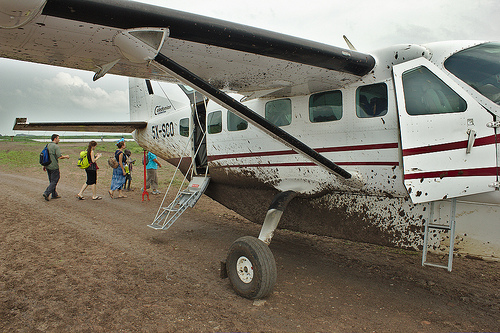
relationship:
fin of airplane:
[0, 93, 115, 156] [97, 15, 454, 283]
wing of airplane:
[31, 19, 353, 110] [97, 15, 454, 283]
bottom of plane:
[219, 187, 464, 266] [97, 15, 454, 283]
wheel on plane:
[204, 214, 295, 319] [213, 83, 441, 226]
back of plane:
[141, 66, 256, 137] [213, 83, 441, 226]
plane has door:
[213, 83, 441, 226] [374, 41, 486, 227]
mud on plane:
[280, 186, 385, 247] [213, 83, 441, 226]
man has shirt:
[14, 120, 81, 229] [30, 143, 85, 167]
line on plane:
[251, 134, 393, 200] [213, 83, 441, 226]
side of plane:
[174, 197, 433, 278] [213, 83, 441, 226]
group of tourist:
[24, 113, 187, 194] [55, 131, 148, 193]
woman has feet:
[72, 139, 111, 198] [62, 195, 106, 212]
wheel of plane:
[204, 214, 295, 319] [213, 83, 441, 226]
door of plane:
[374, 41, 486, 227] [213, 83, 441, 226]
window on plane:
[352, 78, 390, 126] [213, 83, 441, 226]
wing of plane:
[31, 19, 353, 110] [213, 83, 441, 226]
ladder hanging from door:
[421, 197, 462, 269] [374, 41, 486, 227]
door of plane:
[374, 41, 486, 227] [6, 1, 485, 291]